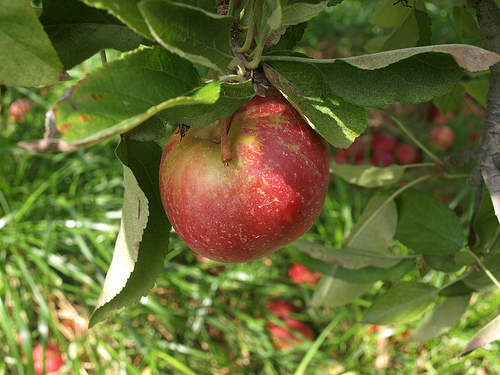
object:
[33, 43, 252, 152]
leaf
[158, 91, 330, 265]
apple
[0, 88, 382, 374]
grass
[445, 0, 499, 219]
stem